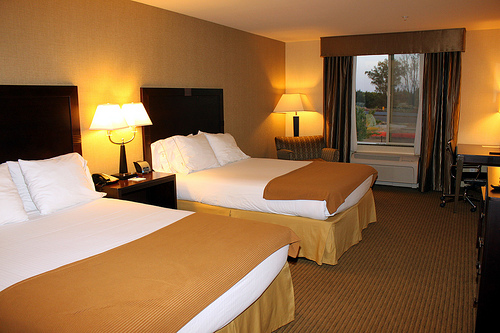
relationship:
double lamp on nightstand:
[89, 102, 153, 180] [94, 169, 179, 213]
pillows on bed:
[152, 130, 252, 175] [139, 85, 378, 266]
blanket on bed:
[262, 160, 378, 214] [139, 85, 378, 266]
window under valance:
[355, 54, 420, 145] [320, 27, 467, 58]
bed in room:
[139, 85, 378, 266] [0, 0, 498, 332]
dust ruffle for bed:
[177, 187, 377, 267] [139, 85, 378, 266]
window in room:
[355, 54, 420, 145] [0, 0, 498, 332]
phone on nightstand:
[91, 172, 120, 191] [94, 169, 179, 213]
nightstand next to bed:
[94, 169, 179, 213] [139, 85, 378, 266]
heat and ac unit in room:
[349, 150, 421, 186] [0, 0, 498, 332]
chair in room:
[274, 135, 341, 162] [0, 0, 498, 332]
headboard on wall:
[140, 86, 225, 171] [0, 0, 287, 178]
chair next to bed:
[274, 135, 341, 162] [139, 85, 378, 266]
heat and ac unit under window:
[349, 150, 421, 186] [355, 54, 420, 145]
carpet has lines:
[267, 185, 482, 332] [270, 184, 481, 332]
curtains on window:
[320, 28, 467, 191] [355, 54, 420, 145]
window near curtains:
[355, 54, 420, 145] [320, 28, 467, 191]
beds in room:
[0, 85, 379, 331] [0, 0, 498, 332]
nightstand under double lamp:
[94, 169, 179, 213] [89, 102, 153, 180]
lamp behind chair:
[272, 93, 315, 136] [274, 135, 341, 162]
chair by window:
[274, 135, 341, 162] [355, 54, 420, 145]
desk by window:
[451, 143, 500, 215] [355, 54, 420, 145]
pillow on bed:
[174, 134, 221, 172] [139, 85, 378, 266]